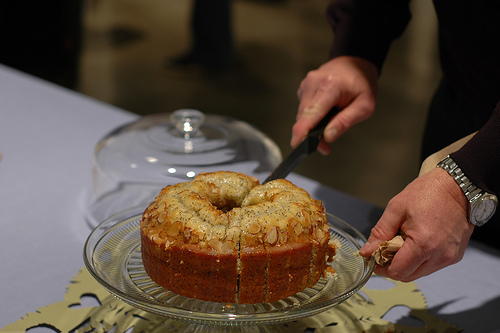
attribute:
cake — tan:
[123, 132, 382, 315]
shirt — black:
[282, 37, 478, 236]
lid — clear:
[82, 102, 282, 232]